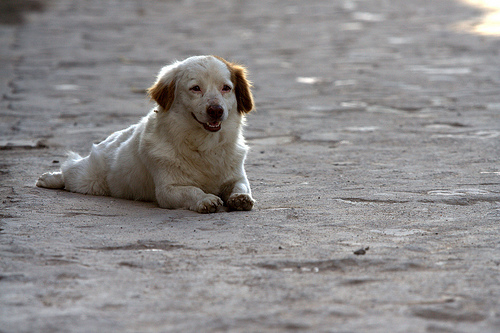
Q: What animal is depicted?
A: Dog.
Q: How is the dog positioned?
A: Reclined on ground.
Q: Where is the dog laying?
A: Ground.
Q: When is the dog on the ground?
A: During the daylight.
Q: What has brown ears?
A: Dog.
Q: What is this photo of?
A: A street.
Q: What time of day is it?
A: It is daytime.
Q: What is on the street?
A: A dog.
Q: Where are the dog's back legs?
A: Behind him.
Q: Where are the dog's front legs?
A: In Front of him.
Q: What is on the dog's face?
A: A doggy smile.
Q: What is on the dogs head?
A: White fur.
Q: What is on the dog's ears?
A: Brown fur.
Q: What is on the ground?
A: Gravel and dirt.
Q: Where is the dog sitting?
A: Ground.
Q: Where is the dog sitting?
A: Ground.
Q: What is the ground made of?
A: Sand.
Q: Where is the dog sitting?
A: Ground.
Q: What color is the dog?
A: White and brown.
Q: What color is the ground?
A: Gray.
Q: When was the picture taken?
A: Daytime.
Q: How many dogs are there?
A: One.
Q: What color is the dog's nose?
A: Black.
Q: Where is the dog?
A: On the ground.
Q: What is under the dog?
A: The ground.